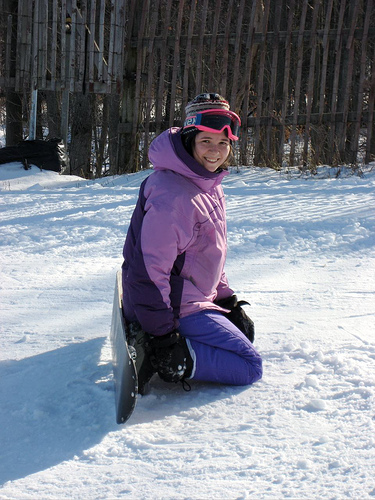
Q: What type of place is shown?
A: It is a field.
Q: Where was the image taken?
A: It was taken at the field.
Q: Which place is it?
A: It is a field.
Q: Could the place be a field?
A: Yes, it is a field.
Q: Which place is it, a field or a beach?
A: It is a field.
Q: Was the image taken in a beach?
A: No, the picture was taken in a field.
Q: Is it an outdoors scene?
A: Yes, it is outdoors.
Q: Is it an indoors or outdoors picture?
A: It is outdoors.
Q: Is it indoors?
A: No, it is outdoors.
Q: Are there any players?
A: No, there are no players.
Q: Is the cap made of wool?
A: Yes, the cap is made of wool.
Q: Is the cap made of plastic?
A: No, the cap is made of wool.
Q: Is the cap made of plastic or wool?
A: The cap is made of wool.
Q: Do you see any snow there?
A: Yes, there is snow.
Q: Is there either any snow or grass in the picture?
A: Yes, there is snow.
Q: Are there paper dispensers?
A: No, there are no paper dispensers.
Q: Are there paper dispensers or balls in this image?
A: No, there are no paper dispensers or balls.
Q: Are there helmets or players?
A: No, there are no players or helmets.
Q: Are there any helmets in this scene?
A: No, there are no helmets.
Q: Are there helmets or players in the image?
A: No, there are no helmets or players.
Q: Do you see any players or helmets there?
A: No, there are no helmets or players.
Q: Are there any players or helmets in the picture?
A: No, there are no helmets or players.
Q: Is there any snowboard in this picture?
A: Yes, there is a snowboard.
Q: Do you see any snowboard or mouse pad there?
A: Yes, there is a snowboard.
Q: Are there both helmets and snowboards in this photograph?
A: No, there is a snowboard but no helmets.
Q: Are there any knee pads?
A: No, there are no knee pads.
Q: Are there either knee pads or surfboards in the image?
A: No, there are no knee pads or surfboards.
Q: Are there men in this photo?
A: No, there are no men.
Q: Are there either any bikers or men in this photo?
A: No, there are no men or bikers.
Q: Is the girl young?
A: Yes, the girl is young.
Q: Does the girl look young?
A: Yes, the girl is young.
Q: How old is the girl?
A: The girl is young.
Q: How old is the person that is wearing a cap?
A: The girl is young.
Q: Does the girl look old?
A: No, the girl is young.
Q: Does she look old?
A: No, the girl is young.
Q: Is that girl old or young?
A: The girl is young.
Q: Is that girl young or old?
A: The girl is young.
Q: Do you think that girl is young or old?
A: The girl is young.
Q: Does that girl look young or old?
A: The girl is young.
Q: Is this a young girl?
A: Yes, this is a young girl.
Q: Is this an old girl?
A: No, this is a young girl.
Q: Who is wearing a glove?
A: The girl is wearing a glove.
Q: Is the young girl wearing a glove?
A: Yes, the girl is wearing a glove.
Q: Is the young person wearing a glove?
A: Yes, the girl is wearing a glove.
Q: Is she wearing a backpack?
A: No, the girl is wearing a glove.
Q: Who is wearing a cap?
A: The girl is wearing a cap.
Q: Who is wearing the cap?
A: The girl is wearing a cap.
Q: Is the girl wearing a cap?
A: Yes, the girl is wearing a cap.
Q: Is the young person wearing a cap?
A: Yes, the girl is wearing a cap.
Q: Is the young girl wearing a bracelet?
A: No, the girl is wearing a cap.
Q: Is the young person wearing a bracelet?
A: No, the girl is wearing a cap.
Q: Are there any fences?
A: Yes, there is a fence.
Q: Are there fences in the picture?
A: Yes, there is a fence.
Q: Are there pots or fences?
A: Yes, there is a fence.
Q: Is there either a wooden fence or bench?
A: Yes, there is a wood fence.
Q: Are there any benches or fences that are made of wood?
A: Yes, the fence is made of wood.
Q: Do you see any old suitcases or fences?
A: Yes, there is an old fence.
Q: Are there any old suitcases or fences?
A: Yes, there is an old fence.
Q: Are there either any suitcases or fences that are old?
A: Yes, the fence is old.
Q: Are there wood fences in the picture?
A: Yes, there is a wood fence.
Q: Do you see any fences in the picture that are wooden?
A: Yes, there is a fence that is wooden.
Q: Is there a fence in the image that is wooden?
A: Yes, there is a fence that is wooden.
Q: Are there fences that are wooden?
A: Yes, there is a fence that is wooden.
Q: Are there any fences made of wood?
A: Yes, there is a fence that is made of wood.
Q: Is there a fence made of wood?
A: Yes, there is a fence that is made of wood.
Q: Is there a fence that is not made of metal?
A: Yes, there is a fence that is made of wood.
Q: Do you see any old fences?
A: Yes, there is an old fence.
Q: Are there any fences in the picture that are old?
A: Yes, there is a fence that is old.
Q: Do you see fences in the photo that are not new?
A: Yes, there is a old fence.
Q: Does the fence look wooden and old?
A: Yes, the fence is wooden and old.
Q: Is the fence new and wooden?
A: No, the fence is wooden but old.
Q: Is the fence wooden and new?
A: No, the fence is wooden but old.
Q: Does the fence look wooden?
A: Yes, the fence is wooden.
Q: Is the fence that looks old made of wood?
A: Yes, the fence is made of wood.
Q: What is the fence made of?
A: The fence is made of wood.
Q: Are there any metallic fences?
A: No, there is a fence but it is wooden.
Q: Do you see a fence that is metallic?
A: No, there is a fence but it is wooden.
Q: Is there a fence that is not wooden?
A: No, there is a fence but it is wooden.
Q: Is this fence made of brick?
A: No, the fence is made of wood.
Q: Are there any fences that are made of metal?
A: No, there is a fence but it is made of wood.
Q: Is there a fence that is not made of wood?
A: No, there is a fence but it is made of wood.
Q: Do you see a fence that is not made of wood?
A: No, there is a fence but it is made of wood.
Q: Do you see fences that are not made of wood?
A: No, there is a fence but it is made of wood.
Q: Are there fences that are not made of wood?
A: No, there is a fence but it is made of wood.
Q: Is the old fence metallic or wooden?
A: The fence is wooden.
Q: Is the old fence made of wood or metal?
A: The fence is made of wood.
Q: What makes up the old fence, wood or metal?
A: The fence is made of wood.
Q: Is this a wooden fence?
A: Yes, this is a wooden fence.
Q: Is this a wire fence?
A: No, this is a wooden fence.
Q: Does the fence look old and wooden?
A: Yes, the fence is old and wooden.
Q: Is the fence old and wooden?
A: Yes, the fence is old and wooden.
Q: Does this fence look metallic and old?
A: No, the fence is old but wooden.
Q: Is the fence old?
A: Yes, the fence is old.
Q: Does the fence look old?
A: Yes, the fence is old.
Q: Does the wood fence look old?
A: Yes, the fence is old.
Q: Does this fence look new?
A: No, the fence is old.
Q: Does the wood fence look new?
A: No, the fence is old.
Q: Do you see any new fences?
A: No, there is a fence but it is old.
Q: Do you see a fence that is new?
A: No, there is a fence but it is old.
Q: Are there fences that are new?
A: No, there is a fence but it is old.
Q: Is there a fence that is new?
A: No, there is a fence but it is old.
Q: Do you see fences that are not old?
A: No, there is a fence but it is old.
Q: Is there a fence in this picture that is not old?
A: No, there is a fence but it is old.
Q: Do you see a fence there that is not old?
A: No, there is a fence but it is old.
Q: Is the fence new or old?
A: The fence is old.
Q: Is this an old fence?
A: Yes, this is an old fence.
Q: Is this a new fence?
A: No, this is an old fence.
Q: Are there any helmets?
A: No, there are no helmets.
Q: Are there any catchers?
A: No, there are no catchers.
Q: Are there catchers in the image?
A: No, there are no catchers.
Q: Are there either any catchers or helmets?
A: No, there are no catchers or helmets.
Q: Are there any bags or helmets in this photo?
A: No, there are no helmets or bags.